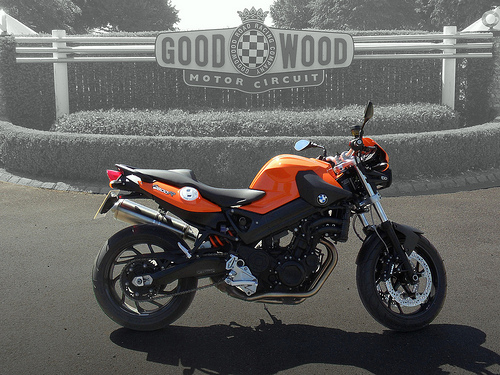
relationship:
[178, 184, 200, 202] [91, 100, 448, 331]
gas tank on bike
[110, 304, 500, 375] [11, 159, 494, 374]
shadow cast on street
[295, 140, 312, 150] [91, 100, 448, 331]
mirror on bike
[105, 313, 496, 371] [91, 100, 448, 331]
shadow of bike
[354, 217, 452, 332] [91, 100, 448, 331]
wheel on bike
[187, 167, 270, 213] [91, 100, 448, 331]
seat on bike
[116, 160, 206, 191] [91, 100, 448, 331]
passenger seat on bike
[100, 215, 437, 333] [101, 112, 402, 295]
tires on bike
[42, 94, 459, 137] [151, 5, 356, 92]
bush under sign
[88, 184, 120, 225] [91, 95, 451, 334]
license plate on back of bike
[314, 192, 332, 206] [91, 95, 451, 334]
logo on bike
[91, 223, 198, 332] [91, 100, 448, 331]
tires on bike